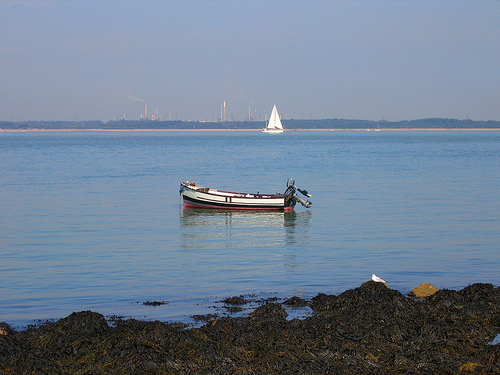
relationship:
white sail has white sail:
[262, 104, 284, 134] [267, 105, 283, 129]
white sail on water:
[262, 104, 284, 134] [3, 129, 499, 317]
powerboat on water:
[177, 181, 312, 213] [3, 129, 499, 317]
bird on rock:
[367, 270, 389, 288] [359, 270, 412, 314]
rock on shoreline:
[359, 270, 412, 314] [2, 276, 499, 374]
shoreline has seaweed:
[2, 276, 499, 374] [2, 287, 499, 373]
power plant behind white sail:
[137, 98, 261, 123] [262, 104, 284, 134]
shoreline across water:
[2, 115, 498, 133] [3, 129, 499, 317]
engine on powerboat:
[283, 177, 311, 209] [177, 181, 312, 213]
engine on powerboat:
[285, 174, 312, 196] [177, 181, 312, 213]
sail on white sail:
[267, 105, 283, 129] [262, 104, 284, 134]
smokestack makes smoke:
[143, 99, 149, 120] [133, 96, 146, 103]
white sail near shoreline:
[262, 104, 284, 134] [2, 115, 498, 133]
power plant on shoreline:
[137, 98, 261, 123] [2, 115, 498, 133]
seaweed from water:
[2, 287, 499, 373] [3, 129, 499, 317]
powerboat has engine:
[177, 181, 312, 213] [283, 177, 311, 209]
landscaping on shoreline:
[3, 117, 498, 128] [2, 115, 498, 133]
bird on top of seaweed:
[367, 270, 389, 288] [2, 287, 499, 373]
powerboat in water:
[177, 181, 312, 213] [3, 129, 499, 317]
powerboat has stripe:
[177, 181, 312, 213] [183, 196, 286, 209]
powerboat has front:
[177, 181, 312, 213] [180, 178, 201, 208]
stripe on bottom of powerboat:
[183, 203, 289, 210] [177, 181, 312, 213]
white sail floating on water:
[262, 104, 284, 134] [3, 129, 499, 317]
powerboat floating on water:
[177, 181, 312, 213] [3, 129, 499, 317]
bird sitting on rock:
[367, 270, 389, 288] [359, 270, 412, 314]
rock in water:
[410, 282, 436, 299] [3, 129, 499, 317]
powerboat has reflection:
[177, 181, 312, 213] [182, 205, 283, 246]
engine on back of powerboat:
[283, 177, 311, 209] [177, 181, 312, 213]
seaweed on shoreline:
[2, 287, 499, 373] [2, 276, 499, 374]